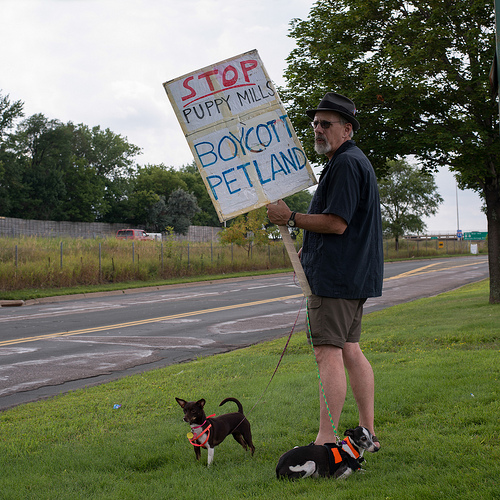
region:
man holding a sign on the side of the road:
[158, 50, 389, 448]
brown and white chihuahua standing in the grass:
[166, 392, 258, 472]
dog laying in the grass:
[274, 420, 384, 487]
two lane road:
[1, 248, 495, 413]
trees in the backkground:
[2, 90, 313, 228]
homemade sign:
[158, 48, 314, 296]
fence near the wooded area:
[1, 213, 228, 247]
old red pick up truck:
[109, 223, 156, 251]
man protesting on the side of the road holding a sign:
[162, 41, 382, 448]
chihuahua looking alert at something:
[173, 393, 256, 471]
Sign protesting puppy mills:
[159, 44, 317, 222]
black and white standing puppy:
[170, 394, 254, 467]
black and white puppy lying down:
[275, 423, 385, 484]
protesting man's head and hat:
[302, 93, 362, 155]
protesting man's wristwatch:
[285, 210, 300, 231]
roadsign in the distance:
[434, 239, 447, 252]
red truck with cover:
[114, 228, 156, 242]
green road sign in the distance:
[457, 230, 488, 240]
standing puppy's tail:
[218, 395, 246, 410]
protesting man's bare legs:
[301, 345, 427, 443]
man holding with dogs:
[159, 59, 432, 487]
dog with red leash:
[162, 387, 257, 469]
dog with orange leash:
[272, 416, 384, 488]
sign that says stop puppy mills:
[137, 49, 318, 229]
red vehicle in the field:
[109, 222, 155, 246]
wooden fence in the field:
[35, 215, 105, 237]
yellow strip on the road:
[66, 301, 121, 393]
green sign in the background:
[452, 224, 485, 257]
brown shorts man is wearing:
[301, 296, 368, 349]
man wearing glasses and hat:
[297, 92, 370, 152]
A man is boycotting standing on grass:
[156, 49, 444, 498]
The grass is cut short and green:
[21, 420, 281, 499]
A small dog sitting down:
[271, 422, 382, 485]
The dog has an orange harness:
[321, 425, 366, 474]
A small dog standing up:
[172, 393, 260, 473]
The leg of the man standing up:
[293, 335, 349, 455]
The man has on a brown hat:
[306, 86, 366, 131]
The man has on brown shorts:
[293, 259, 376, 349]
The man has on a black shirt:
[298, 138, 385, 300]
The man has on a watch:
[284, 208, 301, 232]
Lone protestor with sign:
[121, 24, 441, 486]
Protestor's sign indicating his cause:
[162, 45, 315, 232]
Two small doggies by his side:
[171, 385, 388, 491]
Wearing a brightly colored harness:
[184, 413, 214, 455]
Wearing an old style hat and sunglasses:
[298, 87, 363, 137]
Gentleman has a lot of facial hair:
[308, 131, 351, 156]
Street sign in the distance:
[436, 237, 446, 251]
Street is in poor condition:
[3, 258, 285, 394]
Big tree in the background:
[260, 10, 499, 304]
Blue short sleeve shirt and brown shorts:
[303, 147, 390, 351]